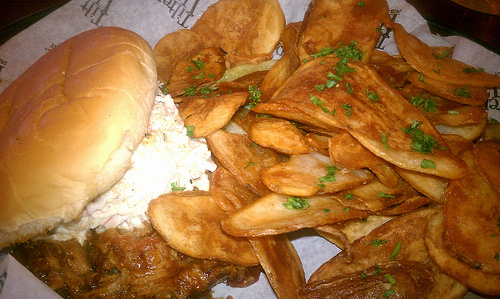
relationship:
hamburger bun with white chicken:
[10, 65, 131, 151] [119, 115, 211, 187]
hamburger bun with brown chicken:
[10, 65, 131, 151] [98, 245, 200, 296]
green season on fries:
[318, 43, 387, 102] [201, 28, 300, 161]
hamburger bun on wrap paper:
[10, 65, 131, 151] [149, 13, 170, 26]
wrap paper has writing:
[149, 13, 170, 26] [77, 2, 109, 26]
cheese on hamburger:
[154, 29, 211, 90] [67, 224, 150, 296]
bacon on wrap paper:
[269, 248, 418, 296] [149, 13, 170, 26]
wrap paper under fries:
[149, 13, 170, 26] [201, 28, 300, 161]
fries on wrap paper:
[201, 28, 300, 161] [149, 13, 170, 26]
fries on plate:
[201, 28, 300, 161] [12, 5, 33, 21]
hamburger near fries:
[67, 224, 150, 296] [201, 28, 300, 161]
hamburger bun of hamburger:
[10, 65, 131, 151] [67, 224, 150, 296]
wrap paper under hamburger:
[149, 13, 170, 26] [67, 224, 150, 296]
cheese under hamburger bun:
[154, 29, 211, 90] [10, 65, 131, 151]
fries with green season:
[201, 28, 300, 161] [318, 43, 387, 102]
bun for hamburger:
[2, 25, 153, 246] [67, 224, 150, 296]